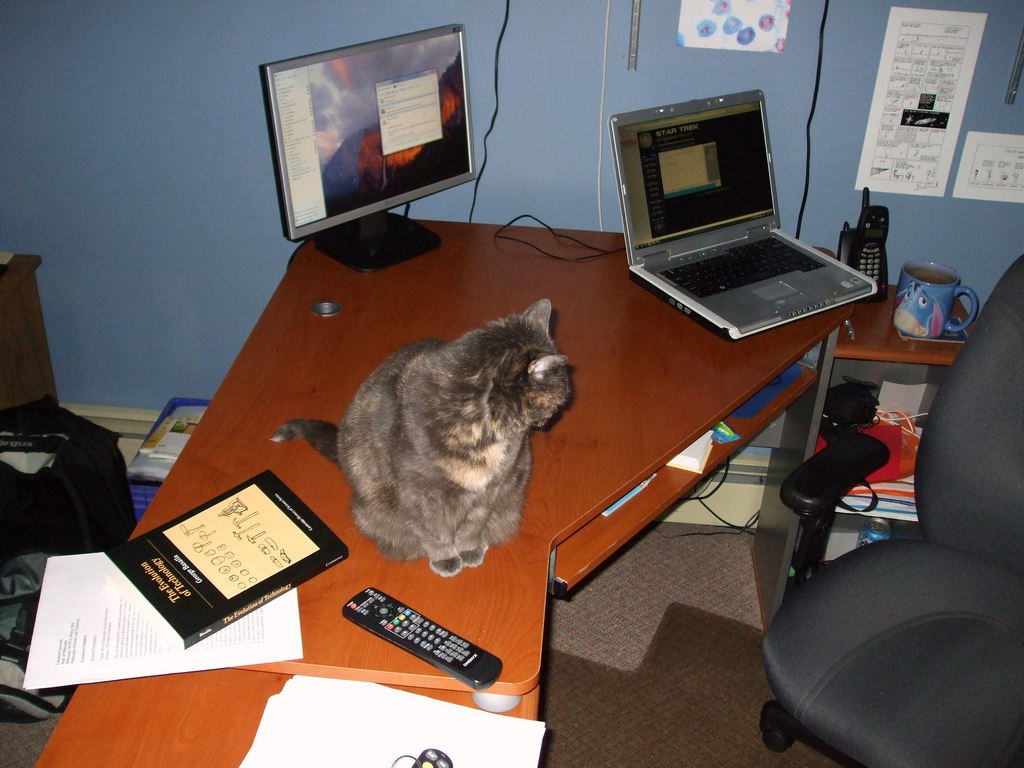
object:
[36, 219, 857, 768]
desk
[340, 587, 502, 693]
control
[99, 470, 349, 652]
book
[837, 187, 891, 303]
phone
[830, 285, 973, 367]
shelf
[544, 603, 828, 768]
mat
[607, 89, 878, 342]
laptop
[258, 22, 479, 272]
desktop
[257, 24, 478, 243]
screen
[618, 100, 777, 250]
screen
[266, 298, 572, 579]
cat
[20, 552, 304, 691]
paper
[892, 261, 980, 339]
mug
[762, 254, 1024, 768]
chair